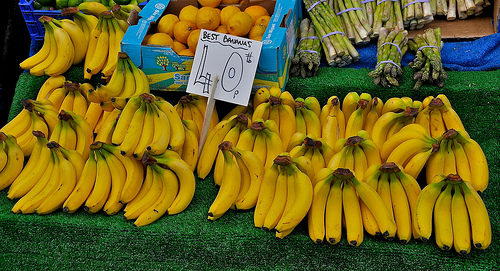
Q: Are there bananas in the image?
A: Yes, there is a banana.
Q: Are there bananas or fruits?
A: Yes, there is a banana.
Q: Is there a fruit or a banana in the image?
A: Yes, there is a banana.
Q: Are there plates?
A: No, there are no plates.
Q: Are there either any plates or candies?
A: No, there are no plates or candies.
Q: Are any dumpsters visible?
A: No, there are no dumpsters.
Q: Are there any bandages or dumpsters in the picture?
A: No, there are no dumpsters or bandages.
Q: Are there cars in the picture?
A: No, there are no cars.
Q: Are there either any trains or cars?
A: No, there are no cars or trains.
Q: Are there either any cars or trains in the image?
A: No, there are no cars or trains.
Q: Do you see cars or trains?
A: No, there are no cars or trains.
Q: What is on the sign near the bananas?
A: The number is on the sign.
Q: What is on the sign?
A: The number is on the sign.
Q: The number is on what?
A: The number is on the sign.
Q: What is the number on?
A: The number is on the sign.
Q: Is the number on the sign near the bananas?
A: Yes, the number is on the sign.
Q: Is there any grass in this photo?
A: Yes, there is grass.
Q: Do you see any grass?
A: Yes, there is grass.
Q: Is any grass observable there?
A: Yes, there is grass.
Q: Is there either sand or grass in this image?
A: Yes, there is grass.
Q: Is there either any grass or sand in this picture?
A: Yes, there is grass.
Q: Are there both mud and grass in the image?
A: No, there is grass but no mud.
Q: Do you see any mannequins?
A: No, there are no mannequins.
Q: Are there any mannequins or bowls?
A: No, there are no mannequins or bowls.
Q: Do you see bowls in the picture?
A: No, there are no bowls.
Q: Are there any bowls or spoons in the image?
A: No, there are no bowls or spoons.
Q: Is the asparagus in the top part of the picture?
A: Yes, the asparagus is in the top of the image.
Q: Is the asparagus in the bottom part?
A: No, the asparagus is in the top of the image.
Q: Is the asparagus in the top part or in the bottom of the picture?
A: The asparagus is in the top of the image.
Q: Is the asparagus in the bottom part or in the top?
A: The asparagus is in the top of the image.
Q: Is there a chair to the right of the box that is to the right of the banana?
A: No, there is an asparagus to the right of the box.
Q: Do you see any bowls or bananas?
A: Yes, there are bananas.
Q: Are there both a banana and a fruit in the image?
A: Yes, there are both a banana and a fruit.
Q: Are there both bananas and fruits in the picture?
A: Yes, there are both bananas and fruits.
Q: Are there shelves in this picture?
A: No, there are no shelves.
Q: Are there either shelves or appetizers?
A: No, there are no shelves or appetizers.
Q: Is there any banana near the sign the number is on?
A: Yes, there are bananas near the sign.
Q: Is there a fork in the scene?
A: No, there are no forks.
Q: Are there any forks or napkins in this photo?
A: No, there are no forks or napkins.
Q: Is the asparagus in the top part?
A: Yes, the asparagus is in the top of the image.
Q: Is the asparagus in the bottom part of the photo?
A: No, the asparagus is in the top of the image.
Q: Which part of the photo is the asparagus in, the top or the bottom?
A: The asparagus is in the top of the image.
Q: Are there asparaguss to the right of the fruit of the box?
A: Yes, there is an asparagus to the right of the fruit.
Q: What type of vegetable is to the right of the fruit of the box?
A: The vegetable is an asparagus.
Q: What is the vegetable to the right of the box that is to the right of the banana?
A: The vegetable is an asparagus.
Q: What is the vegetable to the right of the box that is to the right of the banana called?
A: The vegetable is an asparagus.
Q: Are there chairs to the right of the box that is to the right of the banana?
A: No, there is an asparagus to the right of the box.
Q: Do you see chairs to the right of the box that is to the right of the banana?
A: No, there is an asparagus to the right of the box.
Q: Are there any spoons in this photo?
A: No, there are no spoons.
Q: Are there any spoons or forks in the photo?
A: No, there are no spoons or forks.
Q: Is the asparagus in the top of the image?
A: Yes, the asparagus is in the top of the image.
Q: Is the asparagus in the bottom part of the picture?
A: No, the asparagus is in the top of the image.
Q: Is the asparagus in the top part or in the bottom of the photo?
A: The asparagus is in the top of the image.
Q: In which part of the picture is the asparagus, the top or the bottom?
A: The asparagus is in the top of the image.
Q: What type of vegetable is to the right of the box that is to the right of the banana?
A: The vegetable is an asparagus.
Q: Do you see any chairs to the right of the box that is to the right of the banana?
A: No, there is an asparagus to the right of the box.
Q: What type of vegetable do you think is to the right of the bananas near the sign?
A: The vegetable is an asparagus.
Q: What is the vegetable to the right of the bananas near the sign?
A: The vegetable is an asparagus.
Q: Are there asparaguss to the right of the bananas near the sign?
A: Yes, there is an asparagus to the right of the bananas.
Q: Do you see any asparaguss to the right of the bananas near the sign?
A: Yes, there is an asparagus to the right of the bananas.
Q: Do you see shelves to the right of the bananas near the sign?
A: No, there is an asparagus to the right of the bananas.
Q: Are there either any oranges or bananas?
A: Yes, there is a banana.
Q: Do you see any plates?
A: No, there are no plates.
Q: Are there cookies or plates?
A: No, there are no plates or cookies.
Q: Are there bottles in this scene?
A: No, there are no bottles.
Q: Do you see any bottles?
A: No, there are no bottles.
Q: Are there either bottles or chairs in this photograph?
A: No, there are no bottles or chairs.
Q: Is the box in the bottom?
A: No, the box is in the top of the image.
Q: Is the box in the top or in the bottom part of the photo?
A: The box is in the top of the image.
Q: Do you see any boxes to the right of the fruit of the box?
A: No, the box is to the left of the fruit.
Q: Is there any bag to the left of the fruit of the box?
A: No, there is a box to the left of the fruit.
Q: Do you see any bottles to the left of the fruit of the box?
A: No, there is a box to the left of the fruit.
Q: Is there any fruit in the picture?
A: Yes, there is a fruit.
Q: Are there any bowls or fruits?
A: Yes, there is a fruit.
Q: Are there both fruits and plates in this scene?
A: No, there is a fruit but no plates.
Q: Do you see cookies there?
A: No, there are no cookies.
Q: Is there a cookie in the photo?
A: No, there are no cookies.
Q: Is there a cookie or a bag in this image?
A: No, there are no cookies or bags.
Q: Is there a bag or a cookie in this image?
A: No, there are no cookies or bags.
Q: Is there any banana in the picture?
A: Yes, there is a banana.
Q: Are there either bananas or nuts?
A: Yes, there is a banana.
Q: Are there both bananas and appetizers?
A: No, there is a banana but no appetizers.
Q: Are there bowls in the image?
A: No, there are no bowls.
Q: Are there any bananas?
A: Yes, there is a banana.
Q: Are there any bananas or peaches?
A: Yes, there is a banana.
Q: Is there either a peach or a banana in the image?
A: Yes, there is a banana.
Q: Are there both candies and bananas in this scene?
A: No, there is a banana but no candies.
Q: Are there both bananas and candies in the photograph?
A: No, there is a banana but no candies.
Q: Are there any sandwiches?
A: No, there are no sandwiches.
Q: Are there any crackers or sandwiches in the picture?
A: No, there are no sandwiches or crackers.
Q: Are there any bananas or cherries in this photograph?
A: Yes, there is a banana.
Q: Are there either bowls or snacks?
A: No, there are no bowls or snacks.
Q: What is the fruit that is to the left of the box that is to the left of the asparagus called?
A: The fruit is a banana.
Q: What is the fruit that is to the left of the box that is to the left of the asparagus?
A: The fruit is a banana.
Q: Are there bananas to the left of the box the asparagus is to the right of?
A: Yes, there is a banana to the left of the box.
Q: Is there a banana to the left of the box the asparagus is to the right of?
A: Yes, there is a banana to the left of the box.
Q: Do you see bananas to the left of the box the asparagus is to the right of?
A: Yes, there is a banana to the left of the box.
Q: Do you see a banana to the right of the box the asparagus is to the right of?
A: No, the banana is to the left of the box.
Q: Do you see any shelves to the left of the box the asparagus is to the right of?
A: No, there is a banana to the left of the box.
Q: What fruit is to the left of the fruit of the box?
A: The fruit is a banana.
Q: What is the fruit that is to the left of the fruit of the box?
A: The fruit is a banana.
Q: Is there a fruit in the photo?
A: Yes, there is a fruit.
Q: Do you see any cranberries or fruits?
A: Yes, there is a fruit.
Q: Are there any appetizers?
A: No, there are no appetizers.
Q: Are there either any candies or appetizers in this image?
A: No, there are no appetizers or candies.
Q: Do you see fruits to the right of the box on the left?
A: Yes, there is a fruit to the right of the box.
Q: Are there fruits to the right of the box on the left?
A: Yes, there is a fruit to the right of the box.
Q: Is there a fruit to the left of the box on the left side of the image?
A: No, the fruit is to the right of the box.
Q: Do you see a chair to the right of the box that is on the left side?
A: No, there is a fruit to the right of the box.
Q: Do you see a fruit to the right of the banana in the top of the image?
A: Yes, there is a fruit to the right of the banana.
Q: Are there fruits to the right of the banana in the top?
A: Yes, there is a fruit to the right of the banana.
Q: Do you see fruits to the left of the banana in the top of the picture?
A: No, the fruit is to the right of the banana.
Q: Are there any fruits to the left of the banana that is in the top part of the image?
A: No, the fruit is to the right of the banana.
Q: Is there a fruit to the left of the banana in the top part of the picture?
A: No, the fruit is to the right of the banana.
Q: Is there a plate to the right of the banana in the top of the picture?
A: No, there is a fruit to the right of the banana.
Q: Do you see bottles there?
A: No, there are no bottles.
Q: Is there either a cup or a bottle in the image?
A: No, there are no bottles or cups.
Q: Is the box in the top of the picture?
A: Yes, the box is in the top of the image.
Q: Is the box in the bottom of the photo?
A: No, the box is in the top of the image.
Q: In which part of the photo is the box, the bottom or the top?
A: The box is in the top of the image.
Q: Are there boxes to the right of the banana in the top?
A: Yes, there is a box to the right of the banana.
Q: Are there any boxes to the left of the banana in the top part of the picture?
A: No, the box is to the right of the banana.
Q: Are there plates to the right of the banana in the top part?
A: No, there is a box to the right of the banana.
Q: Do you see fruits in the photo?
A: Yes, there is a fruit.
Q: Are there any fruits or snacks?
A: Yes, there is a fruit.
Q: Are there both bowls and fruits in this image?
A: No, there is a fruit but no bowls.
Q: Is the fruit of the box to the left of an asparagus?
A: Yes, the fruit is to the left of an asparagus.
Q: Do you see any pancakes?
A: No, there are no pancakes.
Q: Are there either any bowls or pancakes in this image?
A: No, there are no pancakes or bowls.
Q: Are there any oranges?
A: Yes, there are oranges.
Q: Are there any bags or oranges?
A: Yes, there are oranges.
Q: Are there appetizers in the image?
A: No, there are no appetizers.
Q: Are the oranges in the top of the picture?
A: Yes, the oranges are in the top of the image.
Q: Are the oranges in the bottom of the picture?
A: No, the oranges are in the top of the image.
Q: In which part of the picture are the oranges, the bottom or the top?
A: The oranges are in the top of the image.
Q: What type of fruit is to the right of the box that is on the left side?
A: The fruits are oranges.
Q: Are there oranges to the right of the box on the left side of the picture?
A: Yes, there are oranges to the right of the box.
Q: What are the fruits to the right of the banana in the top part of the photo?
A: The fruits are oranges.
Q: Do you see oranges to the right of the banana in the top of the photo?
A: Yes, there are oranges to the right of the banana.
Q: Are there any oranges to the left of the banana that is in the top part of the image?
A: No, the oranges are to the right of the banana.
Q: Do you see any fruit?
A: Yes, there is a fruit.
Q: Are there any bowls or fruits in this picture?
A: Yes, there is a fruit.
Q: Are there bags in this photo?
A: No, there are no bags.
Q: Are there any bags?
A: No, there are no bags.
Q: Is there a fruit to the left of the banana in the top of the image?
A: No, the fruit is to the right of the banana.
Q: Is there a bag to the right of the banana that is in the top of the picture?
A: No, there is a fruit to the right of the banana.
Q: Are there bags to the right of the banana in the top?
A: No, there is a fruit to the right of the banana.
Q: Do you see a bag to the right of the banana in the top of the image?
A: No, there is a fruit to the right of the banana.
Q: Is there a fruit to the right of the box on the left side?
A: Yes, there is a fruit to the right of the box.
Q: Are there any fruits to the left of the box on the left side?
A: No, the fruit is to the right of the box.